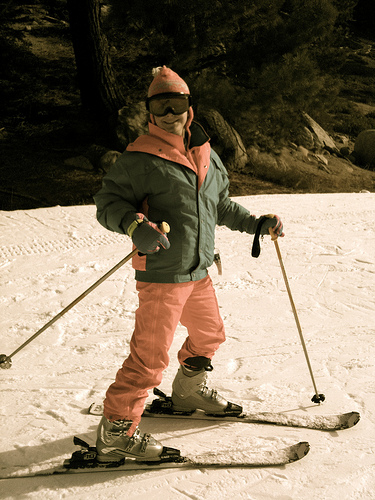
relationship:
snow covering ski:
[243, 410, 343, 429] [89, 397, 360, 431]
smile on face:
[162, 119, 180, 125] [152, 109, 188, 134]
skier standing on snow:
[95, 61, 289, 462] [4, 191, 372, 498]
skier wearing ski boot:
[95, 61, 289, 462] [92, 415, 180, 465]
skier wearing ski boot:
[95, 61, 289, 462] [171, 362, 242, 416]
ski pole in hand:
[267, 223, 329, 405] [256, 214, 285, 241]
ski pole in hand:
[1, 221, 169, 368] [129, 215, 170, 256]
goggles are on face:
[143, 91, 193, 117] [152, 109, 188, 134]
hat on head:
[143, 64, 194, 147] [144, 68, 191, 132]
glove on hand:
[121, 210, 171, 255] [129, 215, 170, 256]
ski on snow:
[89, 397, 360, 431] [4, 191, 372, 498]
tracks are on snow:
[0, 232, 134, 255] [4, 191, 372, 498]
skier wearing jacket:
[95, 61, 289, 462] [93, 120, 255, 284]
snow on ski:
[188, 447, 291, 466] [2, 435, 310, 478]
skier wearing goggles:
[95, 61, 289, 462] [143, 91, 193, 117]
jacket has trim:
[93, 120, 255, 284] [128, 119, 212, 186]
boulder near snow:
[284, 107, 342, 157] [4, 191, 372, 498]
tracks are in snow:
[0, 232, 134, 255] [4, 191, 372, 498]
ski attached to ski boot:
[89, 397, 360, 431] [171, 362, 242, 416]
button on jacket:
[158, 147, 163, 154] [93, 120, 255, 284]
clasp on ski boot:
[140, 433, 151, 454] [92, 415, 180, 465]